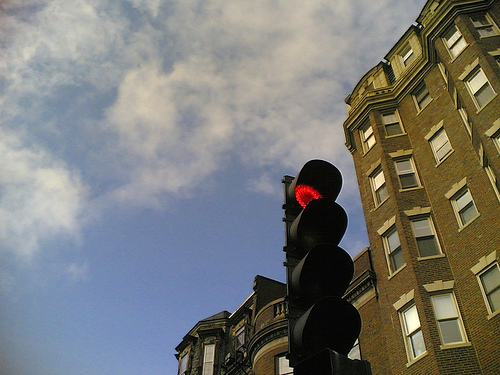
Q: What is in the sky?
A: Clouds.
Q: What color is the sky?
A: Blue.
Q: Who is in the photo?
A: No one.